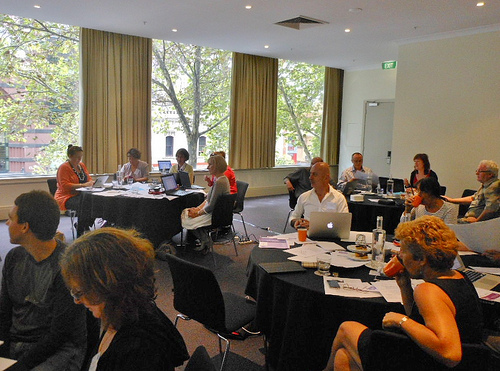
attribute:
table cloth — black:
[75, 186, 200, 225]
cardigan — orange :
[55, 158, 93, 212]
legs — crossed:
[312, 315, 452, 367]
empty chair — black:
[163, 250, 266, 366]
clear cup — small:
[319, 254, 331, 273]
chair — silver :
[160, 242, 274, 364]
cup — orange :
[296, 225, 308, 242]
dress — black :
[354, 270, 493, 367]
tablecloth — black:
[254, 224, 441, 337]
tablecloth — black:
[71, 159, 203, 249]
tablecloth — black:
[299, 163, 457, 243]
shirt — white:
[284, 182, 348, 236]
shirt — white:
[287, 184, 352, 237]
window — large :
[148, 36, 232, 170]